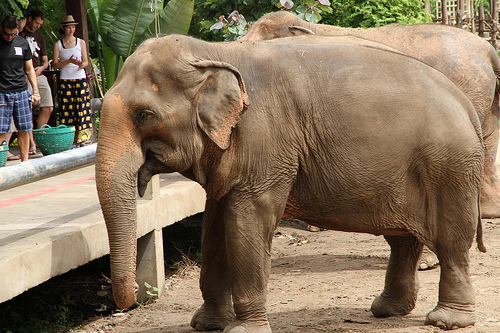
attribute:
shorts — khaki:
[26, 73, 57, 112]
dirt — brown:
[101, 213, 483, 330]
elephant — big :
[97, 33, 479, 328]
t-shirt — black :
[1, 32, 31, 92]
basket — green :
[34, 122, 76, 154]